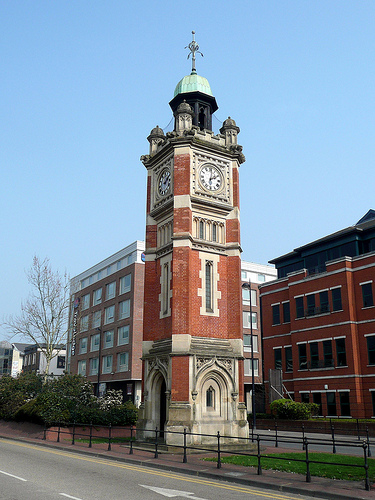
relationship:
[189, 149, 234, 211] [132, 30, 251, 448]
clock in tower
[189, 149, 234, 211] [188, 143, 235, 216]
clock surrounded cement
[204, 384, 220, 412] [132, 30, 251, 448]
window in tower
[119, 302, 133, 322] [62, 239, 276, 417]
window in building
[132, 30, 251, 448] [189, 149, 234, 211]
tower with clock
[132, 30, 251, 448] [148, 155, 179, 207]
tower with clock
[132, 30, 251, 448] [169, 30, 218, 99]
tower has pointy top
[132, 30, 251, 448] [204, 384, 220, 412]
tower with window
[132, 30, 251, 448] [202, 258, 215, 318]
tower with window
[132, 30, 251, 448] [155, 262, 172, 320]
tower with window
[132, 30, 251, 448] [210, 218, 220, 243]
tower with window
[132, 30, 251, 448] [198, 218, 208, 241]
tower with window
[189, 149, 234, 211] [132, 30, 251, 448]
clock on tower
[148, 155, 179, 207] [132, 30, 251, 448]
clock on tower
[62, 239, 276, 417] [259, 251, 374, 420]
building beside building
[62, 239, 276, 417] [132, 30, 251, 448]
building behind tower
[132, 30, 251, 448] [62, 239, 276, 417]
tower in front of building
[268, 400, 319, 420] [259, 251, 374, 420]
bush in front of building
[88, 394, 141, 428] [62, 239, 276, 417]
bush in front of building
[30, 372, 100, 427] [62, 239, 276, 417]
bush in front of building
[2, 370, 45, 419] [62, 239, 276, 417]
bush in front of building